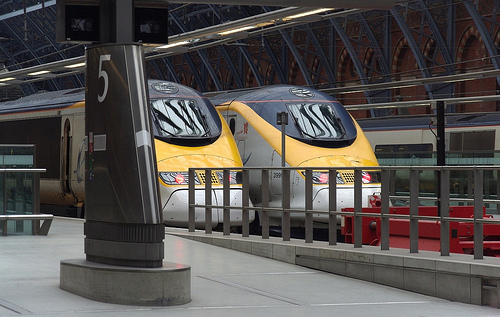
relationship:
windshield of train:
[153, 98, 223, 135] [5, 72, 259, 230]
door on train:
[56, 115, 71, 199] [5, 72, 259, 230]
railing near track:
[368, 161, 470, 237] [253, 214, 463, 272]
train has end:
[203, 84, 381, 240] [250, 94, 390, 209]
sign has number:
[96, 52, 112, 102] [94, 53, 111, 100]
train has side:
[5, 72, 259, 230] [11, 89, 169, 200]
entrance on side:
[56, 114, 76, 202] [11, 89, 169, 200]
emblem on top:
[148, 76, 180, 94] [4, 77, 210, 111]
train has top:
[5, 72, 259, 230] [4, 77, 210, 111]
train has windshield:
[203, 84, 386, 240] [287, 101, 349, 138]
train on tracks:
[0, 72, 259, 231] [232, 215, 485, 265]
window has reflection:
[287, 104, 347, 141] [289, 103, 346, 138]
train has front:
[5, 72, 259, 230] [145, 78, 259, 225]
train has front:
[203, 84, 386, 240] [241, 82, 382, 215]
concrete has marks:
[3, 212, 497, 313] [151, 291, 185, 310]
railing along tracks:
[183, 161, 493, 265] [245, 208, 483, 256]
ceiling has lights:
[1, 0, 484, 71] [3, 0, 323, 84]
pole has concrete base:
[85, 42, 167, 265] [60, 257, 190, 308]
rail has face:
[200, 85, 387, 230] [246, 81, 392, 219]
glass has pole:
[6, 166, 49, 232] [0, 166, 8, 236]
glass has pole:
[6, 166, 49, 232] [14, 169, 24, 231]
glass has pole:
[6, 166, 49, 232] [31, 173, 40, 233]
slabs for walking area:
[0, 266, 361, 315] [0, 214, 443, 315]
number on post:
[95, 52, 112, 102] [82, 0, 165, 270]